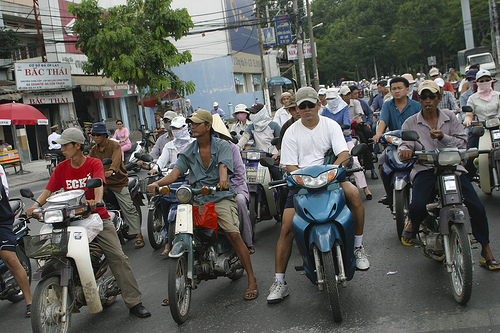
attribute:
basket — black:
[25, 231, 85, 272]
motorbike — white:
[18, 200, 110, 330]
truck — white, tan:
[454, 42, 496, 82]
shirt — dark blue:
[378, 97, 419, 129]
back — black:
[456, 45, 481, 77]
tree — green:
[65, 4, 205, 127]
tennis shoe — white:
[265, 274, 288, 299]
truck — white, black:
[460, 48, 495, 72]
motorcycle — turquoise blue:
[253, 150, 374, 325]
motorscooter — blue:
[276, 155, 361, 310]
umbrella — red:
[0, 100, 48, 175]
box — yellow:
[1, 144, 26, 176]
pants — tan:
[89, 218, 139, 309]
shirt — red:
[45, 153, 110, 218]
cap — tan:
[52, 127, 84, 146]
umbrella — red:
[0, 100, 47, 125]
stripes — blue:
[0, 153, 19, 158]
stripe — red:
[0, 156, 19, 163]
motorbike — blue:
[276, 166, 376, 303]